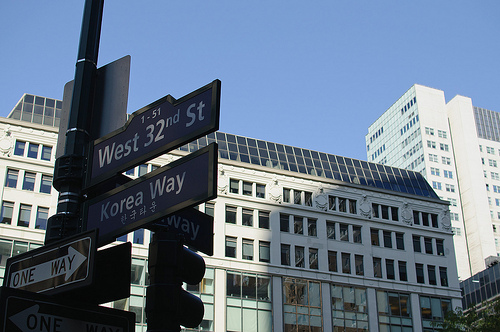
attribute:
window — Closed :
[277, 234, 318, 266]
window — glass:
[428, 209, 440, 226]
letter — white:
[107, 200, 121, 219]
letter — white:
[162, 176, 179, 195]